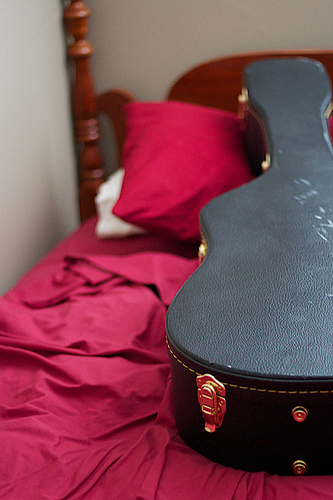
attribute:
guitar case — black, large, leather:
[161, 58, 331, 480]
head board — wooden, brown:
[94, 45, 331, 168]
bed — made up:
[1, 1, 331, 499]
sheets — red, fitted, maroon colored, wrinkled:
[1, 214, 331, 499]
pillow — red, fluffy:
[111, 99, 331, 245]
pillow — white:
[90, 170, 148, 238]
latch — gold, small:
[195, 241, 211, 263]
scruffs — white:
[291, 175, 331, 241]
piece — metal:
[234, 90, 252, 133]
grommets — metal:
[195, 370, 229, 435]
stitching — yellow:
[161, 332, 332, 398]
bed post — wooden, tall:
[59, 1, 108, 228]